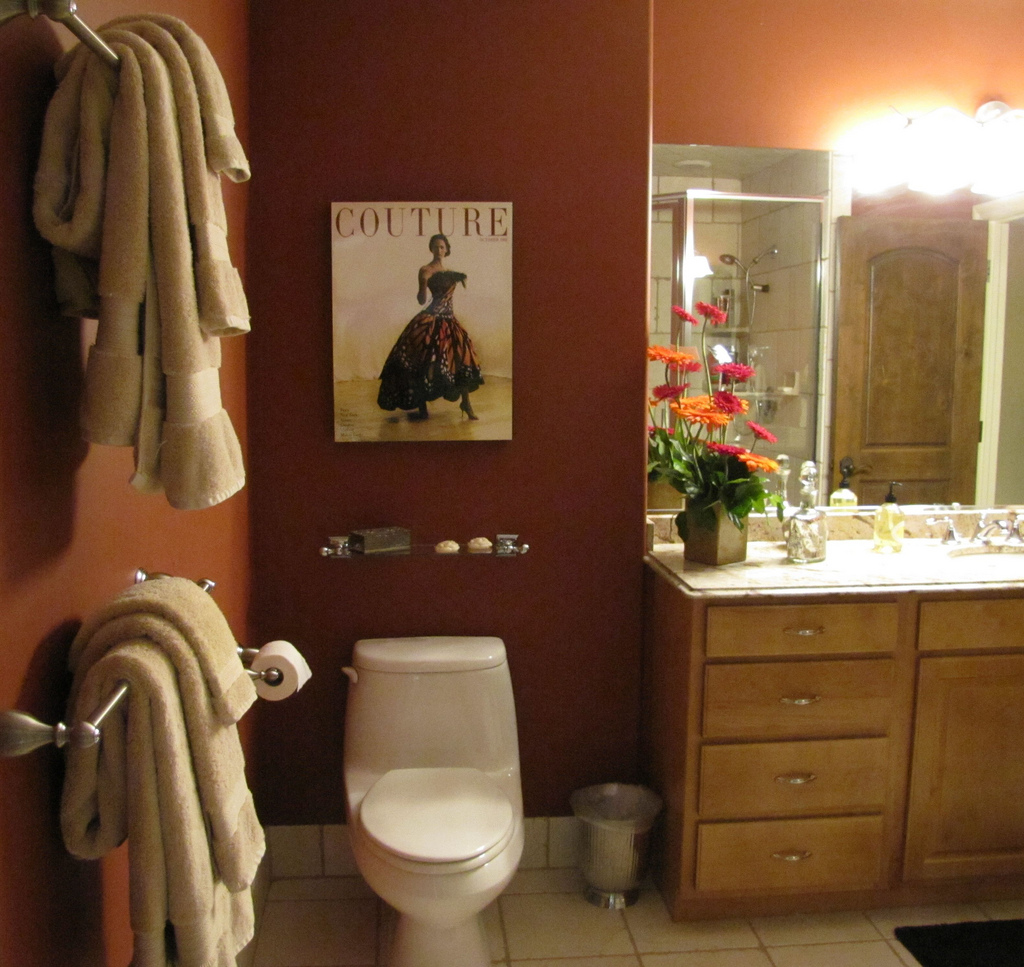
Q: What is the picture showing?
A: It is showing a bathroom.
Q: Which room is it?
A: It is a bathroom.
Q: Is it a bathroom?
A: Yes, it is a bathroom.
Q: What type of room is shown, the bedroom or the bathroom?
A: It is the bathroom.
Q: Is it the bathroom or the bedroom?
A: It is the bathroom.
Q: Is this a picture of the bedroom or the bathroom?
A: It is showing the bathroom.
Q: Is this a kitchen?
A: No, it is a bathroom.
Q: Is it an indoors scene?
A: Yes, it is indoors.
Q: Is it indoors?
A: Yes, it is indoors.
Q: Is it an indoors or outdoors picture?
A: It is indoors.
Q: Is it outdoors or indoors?
A: It is indoors.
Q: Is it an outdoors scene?
A: No, it is indoors.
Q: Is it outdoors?
A: No, it is indoors.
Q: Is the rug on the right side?
A: Yes, the rug is on the right of the image.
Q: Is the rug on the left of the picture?
A: No, the rug is on the right of the image.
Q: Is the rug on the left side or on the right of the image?
A: The rug is on the right of the image.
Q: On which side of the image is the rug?
A: The rug is on the right of the image.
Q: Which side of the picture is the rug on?
A: The rug is on the right of the image.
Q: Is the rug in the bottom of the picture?
A: Yes, the rug is in the bottom of the image.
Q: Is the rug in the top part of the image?
A: No, the rug is in the bottom of the image.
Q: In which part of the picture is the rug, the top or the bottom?
A: The rug is in the bottom of the image.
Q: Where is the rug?
A: The rug is on the floor.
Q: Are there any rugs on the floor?
A: Yes, there is a rug on the floor.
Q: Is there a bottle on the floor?
A: No, there is a rug on the floor.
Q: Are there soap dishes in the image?
A: No, there are no soap dishes.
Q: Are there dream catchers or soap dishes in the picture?
A: No, there are no soap dishes or dream catchers.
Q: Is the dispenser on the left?
A: Yes, the dispenser is on the left of the image.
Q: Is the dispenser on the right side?
A: No, the dispenser is on the left of the image.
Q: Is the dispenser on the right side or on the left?
A: The dispenser is on the left of the image.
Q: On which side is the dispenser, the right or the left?
A: The dispenser is on the left of the image.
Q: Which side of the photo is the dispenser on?
A: The dispenser is on the left of the image.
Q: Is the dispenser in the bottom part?
A: Yes, the dispenser is in the bottom of the image.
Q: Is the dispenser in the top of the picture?
A: No, the dispenser is in the bottom of the image.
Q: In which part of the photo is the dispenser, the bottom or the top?
A: The dispenser is in the bottom of the image.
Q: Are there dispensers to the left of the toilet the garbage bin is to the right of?
A: Yes, there is a dispenser to the left of the toilet.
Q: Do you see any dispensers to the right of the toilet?
A: No, the dispenser is to the left of the toilet.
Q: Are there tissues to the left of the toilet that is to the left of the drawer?
A: No, there is a dispenser to the left of the toilet.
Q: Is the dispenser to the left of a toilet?
A: Yes, the dispenser is to the left of a toilet.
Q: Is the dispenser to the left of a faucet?
A: No, the dispenser is to the left of a toilet.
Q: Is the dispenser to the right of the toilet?
A: No, the dispenser is to the left of the toilet.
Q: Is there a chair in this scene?
A: No, there are no chairs.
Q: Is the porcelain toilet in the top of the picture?
A: No, the toilet is in the bottom of the image.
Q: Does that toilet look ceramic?
A: Yes, the toilet is ceramic.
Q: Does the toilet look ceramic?
A: Yes, the toilet is ceramic.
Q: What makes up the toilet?
A: The toilet is made of porcelain.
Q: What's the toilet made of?
A: The toilet is made of porcelain.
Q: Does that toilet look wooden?
A: No, the toilet is ceramic.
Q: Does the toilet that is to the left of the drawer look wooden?
A: No, the toilet is ceramic.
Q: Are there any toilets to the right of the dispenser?
A: Yes, there is a toilet to the right of the dispenser.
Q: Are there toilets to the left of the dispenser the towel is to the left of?
A: No, the toilet is to the right of the dispenser.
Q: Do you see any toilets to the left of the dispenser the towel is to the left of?
A: No, the toilet is to the right of the dispenser.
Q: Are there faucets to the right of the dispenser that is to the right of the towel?
A: No, there is a toilet to the right of the dispenser.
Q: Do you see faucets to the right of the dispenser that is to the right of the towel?
A: No, there is a toilet to the right of the dispenser.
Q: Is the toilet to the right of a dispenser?
A: Yes, the toilet is to the right of a dispenser.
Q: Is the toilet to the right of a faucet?
A: No, the toilet is to the right of a dispenser.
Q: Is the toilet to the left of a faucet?
A: No, the toilet is to the left of a drawer.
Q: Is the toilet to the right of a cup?
A: No, the toilet is to the right of a towel.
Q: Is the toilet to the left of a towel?
A: No, the toilet is to the right of a towel.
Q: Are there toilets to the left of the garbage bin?
A: Yes, there is a toilet to the left of the garbage bin.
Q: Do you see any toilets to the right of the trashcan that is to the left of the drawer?
A: No, the toilet is to the left of the trash can.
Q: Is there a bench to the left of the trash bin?
A: No, there is a toilet to the left of the trash bin.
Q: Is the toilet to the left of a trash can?
A: Yes, the toilet is to the left of a trash can.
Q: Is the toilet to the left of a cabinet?
A: No, the toilet is to the left of a trash can.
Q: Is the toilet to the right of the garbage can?
A: No, the toilet is to the left of the garbage can.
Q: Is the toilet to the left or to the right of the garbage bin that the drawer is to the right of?
A: The toilet is to the left of the garbage bin.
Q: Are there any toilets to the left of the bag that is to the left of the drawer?
A: Yes, there is a toilet to the left of the bag.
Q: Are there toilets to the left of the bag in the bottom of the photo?
A: Yes, there is a toilet to the left of the bag.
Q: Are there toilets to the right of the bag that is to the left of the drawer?
A: No, the toilet is to the left of the bag.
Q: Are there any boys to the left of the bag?
A: No, there is a toilet to the left of the bag.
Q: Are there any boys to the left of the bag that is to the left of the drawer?
A: No, there is a toilet to the left of the bag.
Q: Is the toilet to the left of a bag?
A: Yes, the toilet is to the left of a bag.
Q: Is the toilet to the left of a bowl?
A: No, the toilet is to the left of a bag.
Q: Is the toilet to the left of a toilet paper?
A: No, the toilet is to the left of a drawer.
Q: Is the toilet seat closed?
A: Yes, the toilet seat is closed.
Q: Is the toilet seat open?
A: No, the toilet seat is closed.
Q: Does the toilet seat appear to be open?
A: No, the toilet seat is closed.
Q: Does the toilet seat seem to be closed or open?
A: The toilet seat is closed.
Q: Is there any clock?
A: No, there are no clocks.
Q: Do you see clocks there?
A: No, there are no clocks.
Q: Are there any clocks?
A: No, there are no clocks.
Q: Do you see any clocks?
A: No, there are no clocks.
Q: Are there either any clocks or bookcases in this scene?
A: No, there are no clocks or bookcases.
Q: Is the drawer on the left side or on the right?
A: The drawer is on the right of the image.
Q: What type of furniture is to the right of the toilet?
A: The piece of furniture is a drawer.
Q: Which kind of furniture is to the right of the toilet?
A: The piece of furniture is a drawer.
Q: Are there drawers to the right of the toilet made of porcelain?
A: Yes, there is a drawer to the right of the toilet.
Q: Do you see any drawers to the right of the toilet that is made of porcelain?
A: Yes, there is a drawer to the right of the toilet.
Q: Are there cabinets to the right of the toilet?
A: No, there is a drawer to the right of the toilet.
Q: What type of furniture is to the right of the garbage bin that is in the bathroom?
A: The piece of furniture is a drawer.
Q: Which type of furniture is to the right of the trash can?
A: The piece of furniture is a drawer.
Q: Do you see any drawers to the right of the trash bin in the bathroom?
A: Yes, there is a drawer to the right of the trash bin.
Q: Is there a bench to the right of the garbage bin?
A: No, there is a drawer to the right of the garbage bin.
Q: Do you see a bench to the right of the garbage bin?
A: No, there is a drawer to the right of the garbage bin.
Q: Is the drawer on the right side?
A: Yes, the drawer is on the right of the image.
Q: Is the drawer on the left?
A: No, the drawer is on the right of the image.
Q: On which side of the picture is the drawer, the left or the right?
A: The drawer is on the right of the image.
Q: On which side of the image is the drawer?
A: The drawer is on the right of the image.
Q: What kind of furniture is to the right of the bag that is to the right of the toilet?
A: The piece of furniture is a drawer.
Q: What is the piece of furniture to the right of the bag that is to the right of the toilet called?
A: The piece of furniture is a drawer.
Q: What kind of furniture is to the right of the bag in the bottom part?
A: The piece of furniture is a drawer.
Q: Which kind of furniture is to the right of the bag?
A: The piece of furniture is a drawer.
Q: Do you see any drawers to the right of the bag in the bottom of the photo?
A: Yes, there is a drawer to the right of the bag.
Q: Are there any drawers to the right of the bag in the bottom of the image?
A: Yes, there is a drawer to the right of the bag.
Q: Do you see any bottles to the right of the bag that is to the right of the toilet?
A: No, there is a drawer to the right of the bag.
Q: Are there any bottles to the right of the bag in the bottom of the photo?
A: No, there is a drawer to the right of the bag.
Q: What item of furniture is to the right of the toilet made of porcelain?
A: The piece of furniture is a drawer.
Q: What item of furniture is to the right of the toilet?
A: The piece of furniture is a drawer.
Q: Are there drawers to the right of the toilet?
A: Yes, there is a drawer to the right of the toilet.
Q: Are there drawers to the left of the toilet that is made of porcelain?
A: No, the drawer is to the right of the toilet.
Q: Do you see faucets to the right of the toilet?
A: No, there is a drawer to the right of the toilet.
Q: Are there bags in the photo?
A: Yes, there is a bag.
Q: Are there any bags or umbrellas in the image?
A: Yes, there is a bag.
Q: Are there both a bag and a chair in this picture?
A: No, there is a bag but no chairs.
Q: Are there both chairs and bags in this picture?
A: No, there is a bag but no chairs.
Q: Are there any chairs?
A: No, there are no chairs.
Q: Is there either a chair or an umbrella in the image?
A: No, there are no chairs or umbrellas.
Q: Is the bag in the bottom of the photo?
A: Yes, the bag is in the bottom of the image.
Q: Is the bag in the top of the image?
A: No, the bag is in the bottom of the image.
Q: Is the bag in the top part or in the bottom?
A: The bag is in the bottom of the image.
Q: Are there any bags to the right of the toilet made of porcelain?
A: Yes, there is a bag to the right of the toilet.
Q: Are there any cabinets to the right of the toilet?
A: No, there is a bag to the right of the toilet.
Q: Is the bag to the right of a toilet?
A: Yes, the bag is to the right of a toilet.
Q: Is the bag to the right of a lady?
A: No, the bag is to the right of a toilet.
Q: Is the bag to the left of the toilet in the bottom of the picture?
A: No, the bag is to the right of the toilet.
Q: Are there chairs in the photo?
A: No, there are no chairs.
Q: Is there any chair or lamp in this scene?
A: No, there are no chairs or lamps.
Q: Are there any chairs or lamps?
A: No, there are no chairs or lamps.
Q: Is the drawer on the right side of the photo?
A: Yes, the drawer is on the right of the image.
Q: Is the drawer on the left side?
A: No, the drawer is on the right of the image.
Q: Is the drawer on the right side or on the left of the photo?
A: The drawer is on the right of the image.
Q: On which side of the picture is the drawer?
A: The drawer is on the right of the image.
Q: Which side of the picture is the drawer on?
A: The drawer is on the right of the image.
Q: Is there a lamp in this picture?
A: No, there are no lamps.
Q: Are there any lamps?
A: No, there are no lamps.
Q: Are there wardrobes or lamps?
A: No, there are no lamps or wardrobes.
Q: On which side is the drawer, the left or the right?
A: The drawer is on the right of the image.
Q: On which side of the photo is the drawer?
A: The drawer is on the right of the image.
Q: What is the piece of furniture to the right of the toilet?
A: The piece of furniture is a drawer.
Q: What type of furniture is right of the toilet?
A: The piece of furniture is a drawer.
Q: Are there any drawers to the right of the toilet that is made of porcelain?
A: Yes, there is a drawer to the right of the toilet.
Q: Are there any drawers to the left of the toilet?
A: No, the drawer is to the right of the toilet.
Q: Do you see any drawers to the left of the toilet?
A: No, the drawer is to the right of the toilet.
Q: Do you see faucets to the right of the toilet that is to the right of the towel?
A: No, there is a drawer to the right of the toilet.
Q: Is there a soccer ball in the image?
A: No, there are no soccer balls.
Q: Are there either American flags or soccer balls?
A: No, there are no soccer balls or American flags.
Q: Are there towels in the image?
A: Yes, there is a towel.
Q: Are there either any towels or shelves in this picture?
A: Yes, there is a towel.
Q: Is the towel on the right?
A: No, the towel is on the left of the image.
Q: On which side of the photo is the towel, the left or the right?
A: The towel is on the left of the image.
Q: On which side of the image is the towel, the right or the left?
A: The towel is on the left of the image.